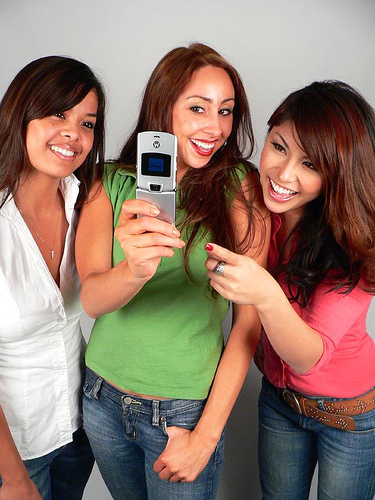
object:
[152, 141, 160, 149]
button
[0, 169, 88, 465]
white shirt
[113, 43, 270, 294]
hair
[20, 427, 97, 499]
blue jeans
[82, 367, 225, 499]
blue jeans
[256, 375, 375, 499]
blue jeans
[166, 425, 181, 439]
thumb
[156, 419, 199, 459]
pocket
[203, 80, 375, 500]
female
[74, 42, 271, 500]
female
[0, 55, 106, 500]
female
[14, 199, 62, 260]
necklace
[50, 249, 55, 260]
charm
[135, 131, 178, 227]
camera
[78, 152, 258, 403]
t-shirt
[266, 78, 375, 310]
darl hair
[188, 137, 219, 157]
lipstick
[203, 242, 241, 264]
finger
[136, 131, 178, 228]
phone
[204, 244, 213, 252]
polish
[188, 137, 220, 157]
smile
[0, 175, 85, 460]
blouse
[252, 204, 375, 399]
shirt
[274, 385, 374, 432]
belt